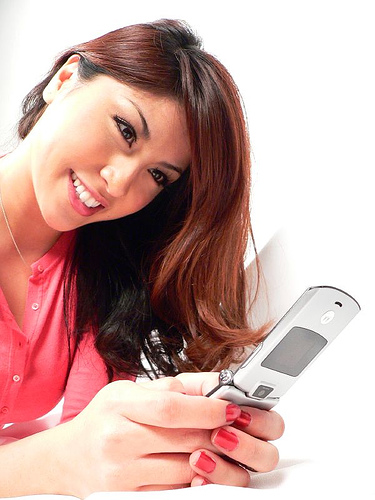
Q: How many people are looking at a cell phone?
A: One.